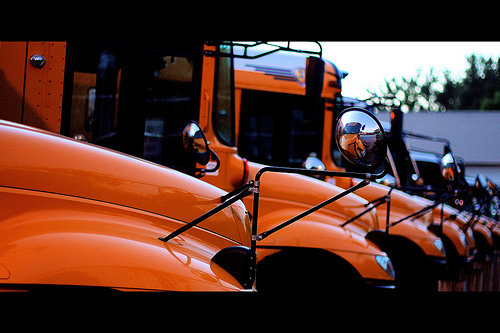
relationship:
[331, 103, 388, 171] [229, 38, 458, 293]
mirror on bus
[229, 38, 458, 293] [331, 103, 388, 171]
bus with a mirror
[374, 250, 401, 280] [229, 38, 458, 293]
light on bus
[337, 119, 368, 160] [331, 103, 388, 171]
reflection on mirror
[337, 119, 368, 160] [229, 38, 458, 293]
reflection on bus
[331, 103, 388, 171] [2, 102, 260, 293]
mirror on schoolbus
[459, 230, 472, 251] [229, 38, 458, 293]
signal on bus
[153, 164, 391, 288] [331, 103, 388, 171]
bracket holding mirror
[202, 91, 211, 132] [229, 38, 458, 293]
handle on bus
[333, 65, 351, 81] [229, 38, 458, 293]
reflector on bus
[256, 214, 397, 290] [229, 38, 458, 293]
fender on bus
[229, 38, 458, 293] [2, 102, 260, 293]
bus by schoolbus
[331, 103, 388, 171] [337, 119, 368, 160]
mirror with reflection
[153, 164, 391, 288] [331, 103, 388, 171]
bracket holding up mirror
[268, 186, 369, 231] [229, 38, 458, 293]
shadow on bus